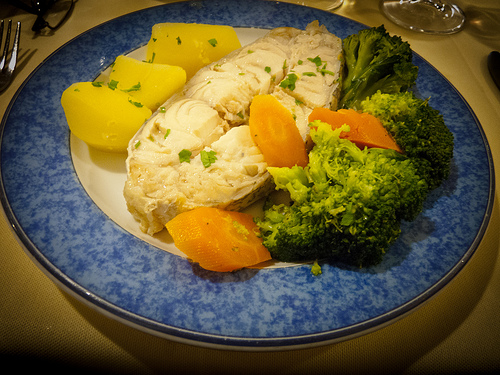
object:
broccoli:
[257, 22, 454, 273]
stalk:
[266, 163, 313, 202]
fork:
[0, 14, 22, 95]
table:
[0, 0, 499, 374]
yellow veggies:
[60, 82, 152, 153]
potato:
[142, 21, 243, 79]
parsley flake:
[208, 38, 218, 47]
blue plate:
[0, 0, 493, 352]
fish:
[123, 18, 346, 236]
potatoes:
[107, 53, 188, 111]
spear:
[335, 22, 417, 111]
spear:
[351, 89, 455, 187]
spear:
[253, 119, 426, 271]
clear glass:
[377, 3, 466, 34]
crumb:
[310, 258, 322, 275]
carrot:
[241, 92, 316, 189]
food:
[58, 18, 454, 275]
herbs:
[92, 69, 143, 108]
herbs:
[278, 55, 336, 92]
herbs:
[177, 147, 191, 165]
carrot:
[168, 209, 275, 274]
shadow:
[58, 192, 500, 374]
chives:
[199, 149, 219, 168]